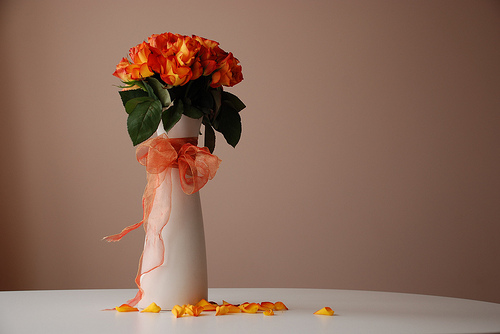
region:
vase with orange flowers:
[94, 14, 266, 306]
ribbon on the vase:
[143, 129, 219, 218]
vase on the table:
[110, 121, 222, 313]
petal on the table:
[315, 292, 340, 319]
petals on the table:
[259, 298, 286, 321]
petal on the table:
[141, 298, 157, 320]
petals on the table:
[172, 293, 199, 320]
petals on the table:
[213, 290, 258, 318]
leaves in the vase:
[201, 79, 241, 144]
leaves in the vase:
[117, 88, 161, 136]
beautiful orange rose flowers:
[107, 35, 284, 300]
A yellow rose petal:
[305, 300, 343, 317]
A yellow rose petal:
[110, 293, 136, 315]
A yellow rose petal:
[140, 298, 163, 318]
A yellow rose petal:
[169, 299, 182, 319]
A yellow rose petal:
[186, 301, 196, 315]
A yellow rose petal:
[212, 294, 236, 314]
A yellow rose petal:
[233, 293, 257, 318]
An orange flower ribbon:
[125, 128, 228, 192]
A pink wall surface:
[282, 60, 446, 238]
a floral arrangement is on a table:
[106, 26, 255, 316]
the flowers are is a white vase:
[113, 30, 246, 315]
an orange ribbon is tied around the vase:
[132, 108, 215, 308]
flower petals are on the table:
[113, 288, 340, 323]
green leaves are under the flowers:
[119, 76, 246, 151]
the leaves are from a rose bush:
[118, 78, 248, 156]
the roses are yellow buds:
[108, 29, 246, 95]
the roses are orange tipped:
[106, 32, 243, 93]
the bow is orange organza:
[98, 131, 223, 298]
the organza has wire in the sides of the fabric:
[101, 136, 220, 311]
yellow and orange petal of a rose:
[313, 303, 336, 320]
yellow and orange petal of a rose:
[112, 297, 136, 313]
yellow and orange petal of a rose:
[138, 299, 165, 314]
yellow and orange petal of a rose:
[168, 299, 183, 320]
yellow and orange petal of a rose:
[211, 301, 234, 320]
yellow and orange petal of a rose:
[258, 305, 275, 320]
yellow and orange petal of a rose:
[271, 297, 288, 314]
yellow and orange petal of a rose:
[237, 299, 262, 314]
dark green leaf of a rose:
[122, 94, 161, 147]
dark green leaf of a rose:
[200, 122, 217, 154]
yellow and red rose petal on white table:
[309, 302, 339, 317]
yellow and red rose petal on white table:
[268, 296, 288, 313]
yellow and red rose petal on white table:
[260, 306, 276, 317]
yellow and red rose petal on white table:
[138, 299, 163, 314]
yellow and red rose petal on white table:
[113, 300, 142, 316]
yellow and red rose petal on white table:
[194, 295, 216, 315]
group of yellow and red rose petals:
[167, 297, 291, 322]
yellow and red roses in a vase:
[106, 22, 244, 316]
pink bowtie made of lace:
[91, 133, 221, 317]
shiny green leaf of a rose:
[120, 92, 163, 149]